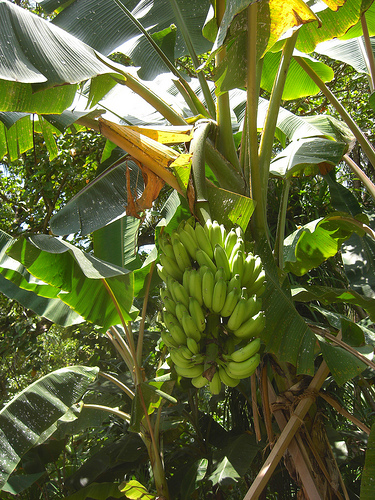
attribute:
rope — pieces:
[268, 384, 348, 498]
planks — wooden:
[227, 320, 349, 494]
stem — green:
[198, 311, 222, 360]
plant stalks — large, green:
[151, 49, 317, 269]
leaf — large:
[1, 0, 190, 126]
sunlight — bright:
[70, 65, 188, 126]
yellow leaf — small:
[81, 108, 196, 226]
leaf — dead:
[211, 0, 268, 94]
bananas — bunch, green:
[122, 202, 309, 420]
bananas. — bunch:
[149, 220, 269, 314]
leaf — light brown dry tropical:
[98, 116, 196, 216]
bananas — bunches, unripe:
[155, 201, 270, 396]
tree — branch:
[4, 6, 364, 497]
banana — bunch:
[151, 221, 265, 392]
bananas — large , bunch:
[149, 218, 270, 401]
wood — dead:
[242, 350, 340, 493]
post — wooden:
[254, 371, 325, 498]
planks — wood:
[225, 369, 338, 478]